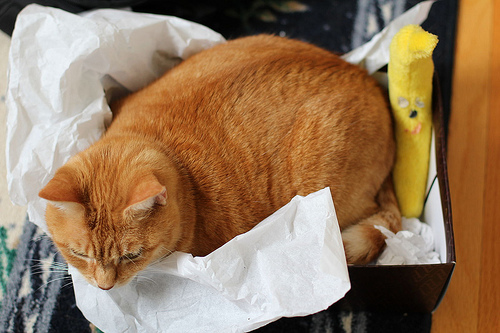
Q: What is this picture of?
A: A cat.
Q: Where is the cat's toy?
A: In the back of the box.